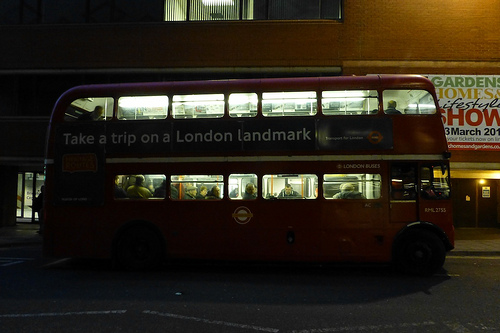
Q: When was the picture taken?
A: Evening.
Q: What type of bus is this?
A: Double Decker.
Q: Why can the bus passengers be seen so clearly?
A: Lights are on inside bus.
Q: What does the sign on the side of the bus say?
A: Take a trip on a London landmark.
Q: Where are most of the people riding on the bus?
A: Lower level.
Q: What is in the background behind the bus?
A: Building.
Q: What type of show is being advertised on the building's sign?
A: Garden and Home show.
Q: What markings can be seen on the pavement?
A: White lines.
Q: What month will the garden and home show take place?
A: March.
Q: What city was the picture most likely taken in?
A: London.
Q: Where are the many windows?
A: The bus.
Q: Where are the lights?
A: On bus.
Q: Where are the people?
A: On bus.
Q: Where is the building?
A: Behind the bus.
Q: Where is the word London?
A: On bus.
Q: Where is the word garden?
A: On building.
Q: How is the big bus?
A: Red.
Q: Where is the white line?
A: On road.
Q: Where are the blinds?
A: Window in building.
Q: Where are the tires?
A: On the bus.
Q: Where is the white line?
A: On the pavement.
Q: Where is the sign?
A: On the bus.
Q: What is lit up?
A: The interior of the bus.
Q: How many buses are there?
A: One.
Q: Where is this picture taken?
A: London.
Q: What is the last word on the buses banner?
A: Landmark.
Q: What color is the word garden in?
A: Green.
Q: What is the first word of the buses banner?
A: Take.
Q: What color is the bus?
A: Red.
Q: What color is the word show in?
A: Red.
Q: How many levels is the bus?
A: Two.